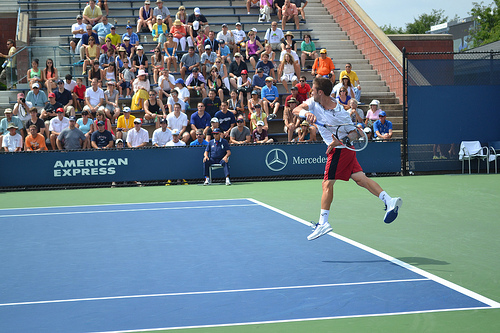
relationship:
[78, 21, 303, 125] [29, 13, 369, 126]
spectators sitting in stand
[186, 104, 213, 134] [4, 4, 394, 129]
spectator sitting in stand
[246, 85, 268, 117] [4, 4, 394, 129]
spectator sitting in stand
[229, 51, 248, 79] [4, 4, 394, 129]
spectator sitting in stand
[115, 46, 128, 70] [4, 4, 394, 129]
spectator sitting in stand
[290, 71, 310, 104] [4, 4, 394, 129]
spectator sitting in stand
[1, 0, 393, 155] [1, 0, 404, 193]
spectators sitting in stand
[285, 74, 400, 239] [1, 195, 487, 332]
man playing tennis on court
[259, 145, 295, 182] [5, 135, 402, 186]
emblem on sign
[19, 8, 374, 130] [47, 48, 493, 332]
crowd watching tennis game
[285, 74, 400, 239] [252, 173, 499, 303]
man above line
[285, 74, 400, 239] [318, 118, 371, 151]
man swing racket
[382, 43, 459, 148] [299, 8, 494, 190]
wall on building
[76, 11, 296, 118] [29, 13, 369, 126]
spectators in stand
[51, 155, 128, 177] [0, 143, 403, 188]
american express on sign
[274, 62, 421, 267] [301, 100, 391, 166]
man holds racket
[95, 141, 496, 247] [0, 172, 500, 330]
edging of court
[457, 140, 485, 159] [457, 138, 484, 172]
towel draped over chair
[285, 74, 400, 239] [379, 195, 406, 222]
man wearing tennis shoe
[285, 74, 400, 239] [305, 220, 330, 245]
man wearing tennis shoe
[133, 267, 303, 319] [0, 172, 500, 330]
line on court